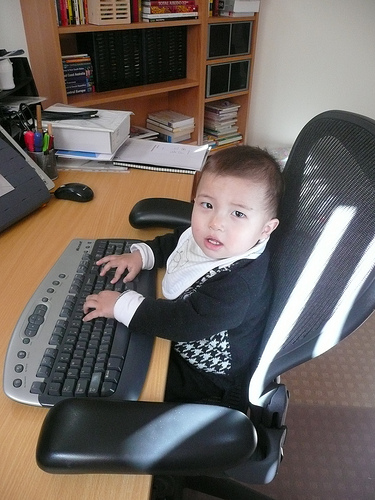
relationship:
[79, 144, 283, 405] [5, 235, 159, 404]
boy typing on keyboard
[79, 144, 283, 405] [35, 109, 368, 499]
toddler in chair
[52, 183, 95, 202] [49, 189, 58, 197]
mouse has cord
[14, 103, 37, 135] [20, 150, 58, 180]
scissors in holder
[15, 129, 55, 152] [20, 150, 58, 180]
markers in holder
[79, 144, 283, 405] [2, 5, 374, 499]
toddler in home office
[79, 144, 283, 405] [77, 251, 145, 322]
boy has hands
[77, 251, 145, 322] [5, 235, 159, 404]
hands on keyboard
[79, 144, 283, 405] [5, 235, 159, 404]
boy playing on keyboard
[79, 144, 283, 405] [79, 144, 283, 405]
baby has boy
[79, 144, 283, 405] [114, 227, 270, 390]
boy has shirt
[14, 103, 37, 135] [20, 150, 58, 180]
scissors in pencil cup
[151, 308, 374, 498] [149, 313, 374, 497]
floor has carpet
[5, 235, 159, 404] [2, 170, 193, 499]
keyboard on desk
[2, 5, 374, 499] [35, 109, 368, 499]
room has chair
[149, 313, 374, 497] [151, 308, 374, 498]
tiles on floor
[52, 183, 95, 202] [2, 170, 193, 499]
mouse on desk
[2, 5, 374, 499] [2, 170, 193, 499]
room has desk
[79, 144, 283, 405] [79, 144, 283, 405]
boy has boy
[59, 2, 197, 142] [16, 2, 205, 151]
books on bookshelf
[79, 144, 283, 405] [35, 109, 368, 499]
baby in chair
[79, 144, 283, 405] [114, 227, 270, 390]
baby has sweater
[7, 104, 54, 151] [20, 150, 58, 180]
office supplies in holder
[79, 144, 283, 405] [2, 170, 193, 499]
baby sitting at desk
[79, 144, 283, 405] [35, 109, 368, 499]
baby sitting in chair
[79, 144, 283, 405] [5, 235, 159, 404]
baby typing on keyboard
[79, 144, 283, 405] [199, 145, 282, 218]
baby has brown hair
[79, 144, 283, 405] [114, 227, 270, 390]
boy has sweater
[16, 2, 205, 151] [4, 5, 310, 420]
bookshelf in photo